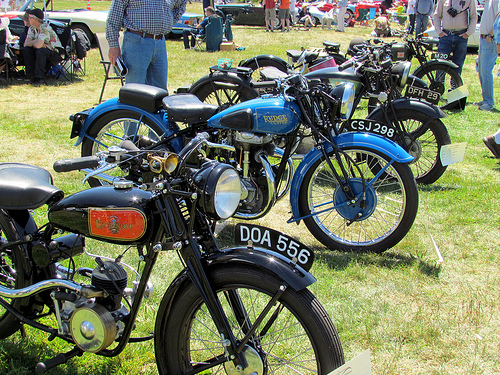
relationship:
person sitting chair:
[13, 5, 67, 85] [33, 15, 79, 84]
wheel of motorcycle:
[298, 147, 415, 257] [114, 73, 424, 253]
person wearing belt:
[94, 0, 179, 98] [124, 20, 170, 45]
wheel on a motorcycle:
[298, 147, 415, 257] [114, 73, 424, 253]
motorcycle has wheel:
[114, 73, 424, 253] [298, 147, 415, 257]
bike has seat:
[65, 61, 417, 264] [155, 85, 209, 125]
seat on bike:
[155, 85, 209, 125] [65, 61, 417, 264]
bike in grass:
[65, 61, 417, 264] [4, 4, 491, 372]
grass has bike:
[4, 4, 491, 372] [65, 61, 417, 264]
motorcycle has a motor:
[114, 73, 424, 253] [204, 105, 303, 132]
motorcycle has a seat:
[114, 73, 424, 253] [167, 95, 203, 115]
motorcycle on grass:
[114, 73, 424, 253] [88, 103, 485, 372]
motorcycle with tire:
[114, 73, 424, 253] [300, 146, 417, 252]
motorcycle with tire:
[114, 73, 424, 253] [81, 109, 173, 189]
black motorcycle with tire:
[1, 144, 343, 372] [164, 263, 342, 373]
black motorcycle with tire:
[1, 144, 343, 372] [300, 144, 422, 261]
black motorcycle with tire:
[1, 144, 343, 372] [0, 207, 44, 337]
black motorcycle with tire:
[1, 144, 343, 372] [370, 114, 451, 185]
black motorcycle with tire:
[1, 144, 343, 372] [82, 107, 177, 192]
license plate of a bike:
[235, 222, 315, 273] [1, 129, 357, 374]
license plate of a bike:
[343, 119, 396, 136] [65, 61, 417, 264]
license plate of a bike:
[401, 86, 444, 106] [175, 39, 455, 194]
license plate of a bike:
[430, 51, 450, 60] [289, 31, 469, 114]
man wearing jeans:
[106, 0, 188, 146] [121, 34, 168, 139]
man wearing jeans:
[432, 0, 476, 90] [435, 30, 467, 86]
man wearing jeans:
[477, 0, 489, 109] [480, 35, 490, 111]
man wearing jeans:
[415, 1, 432, 33] [414, 12, 428, 35]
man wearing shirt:
[106, 0, 188, 146] [106, 0, 188, 47]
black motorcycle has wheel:
[1, 144, 343, 372] [146, 256, 343, 373]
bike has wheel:
[65, 61, 417, 264] [295, 152, 428, 257]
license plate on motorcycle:
[343, 119, 396, 136] [47, 42, 422, 256]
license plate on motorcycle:
[235, 222, 315, 273] [2, 129, 357, 373]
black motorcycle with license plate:
[1, 144, 343, 372] [235, 222, 315, 273]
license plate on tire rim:
[235, 222, 315, 273] [209, 246, 317, 290]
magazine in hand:
[112, 55, 128, 76] [102, 36, 129, 69]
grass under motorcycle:
[4, 4, 491, 372] [2, 129, 357, 373]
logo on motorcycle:
[86, 200, 151, 250] [2, 129, 357, 373]